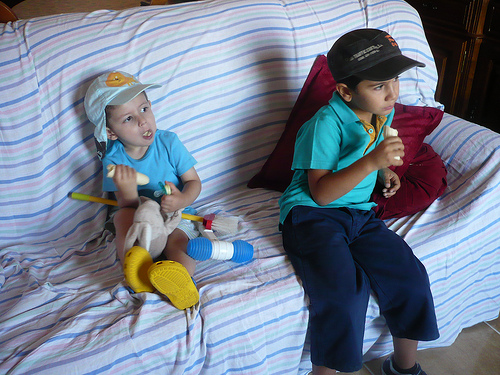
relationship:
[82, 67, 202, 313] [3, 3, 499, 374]
child on couch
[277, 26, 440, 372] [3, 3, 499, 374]
child on couch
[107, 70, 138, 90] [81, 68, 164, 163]
goldfish on hat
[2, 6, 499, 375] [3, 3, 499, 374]
blanket on couch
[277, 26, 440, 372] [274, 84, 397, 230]
child wears shirt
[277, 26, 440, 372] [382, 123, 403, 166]
child holds banana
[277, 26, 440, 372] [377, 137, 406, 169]
child has right hand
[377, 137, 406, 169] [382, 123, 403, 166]
right hand holds banana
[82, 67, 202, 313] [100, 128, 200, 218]
child wears shirt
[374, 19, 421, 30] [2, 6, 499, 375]
stripe on blanket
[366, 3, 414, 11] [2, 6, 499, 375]
stripe on blanket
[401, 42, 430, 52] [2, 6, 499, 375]
stripe on blanket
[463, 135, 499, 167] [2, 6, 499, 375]
stripe on blanket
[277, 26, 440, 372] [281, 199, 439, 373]
child wears pants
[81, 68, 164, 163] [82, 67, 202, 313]
hat on child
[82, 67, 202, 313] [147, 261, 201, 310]
child wears shoe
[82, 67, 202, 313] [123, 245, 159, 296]
child wears shoe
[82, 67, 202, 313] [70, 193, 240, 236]
child has toy broom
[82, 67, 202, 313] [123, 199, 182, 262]
child has toy rabbit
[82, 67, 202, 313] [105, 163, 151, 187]
child eats banana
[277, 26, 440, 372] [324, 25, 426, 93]
child wears hat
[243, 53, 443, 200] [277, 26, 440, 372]
pillow under child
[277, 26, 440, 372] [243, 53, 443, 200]
child leans on pillow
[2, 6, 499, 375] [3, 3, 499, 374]
blanket over couch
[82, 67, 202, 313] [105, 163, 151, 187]
child eating banana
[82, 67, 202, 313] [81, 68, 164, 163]
child wears hat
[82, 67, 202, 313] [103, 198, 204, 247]
child has lap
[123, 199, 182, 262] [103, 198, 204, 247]
toy rabbit on lap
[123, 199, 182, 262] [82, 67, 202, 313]
toy rabbit on child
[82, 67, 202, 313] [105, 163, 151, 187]
child holds banana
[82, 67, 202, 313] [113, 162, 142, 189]
child has right hand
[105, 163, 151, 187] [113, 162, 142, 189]
banana in right hand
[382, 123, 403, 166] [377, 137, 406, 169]
banana in right hand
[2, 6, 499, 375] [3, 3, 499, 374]
blanket covers couch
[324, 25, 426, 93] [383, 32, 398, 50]
hat has logo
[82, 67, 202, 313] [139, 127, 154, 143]
child has mouth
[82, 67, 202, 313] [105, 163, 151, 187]
child chewing banana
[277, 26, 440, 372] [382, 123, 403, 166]
child eats banana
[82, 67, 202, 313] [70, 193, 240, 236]
child holds toy broom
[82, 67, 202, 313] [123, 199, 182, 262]
child holds toy rabbit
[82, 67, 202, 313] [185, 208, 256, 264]
child holds toy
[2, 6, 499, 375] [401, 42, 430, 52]
blanket has stripe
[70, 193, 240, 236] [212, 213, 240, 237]
toy broom has bristles